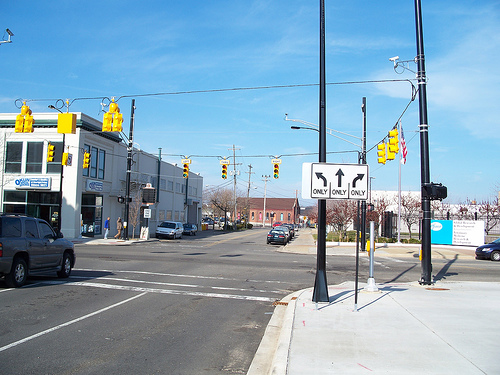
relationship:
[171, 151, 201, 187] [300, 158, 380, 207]
light near sign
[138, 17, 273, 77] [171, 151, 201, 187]
sky above light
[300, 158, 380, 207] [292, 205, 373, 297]
sign on pole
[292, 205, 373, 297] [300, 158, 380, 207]
pole on sign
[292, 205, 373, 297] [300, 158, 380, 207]
pole holding sign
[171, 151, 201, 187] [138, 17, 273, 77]
light below sky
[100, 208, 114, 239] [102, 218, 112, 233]
man wearing shirt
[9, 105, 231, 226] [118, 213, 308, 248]
building along street